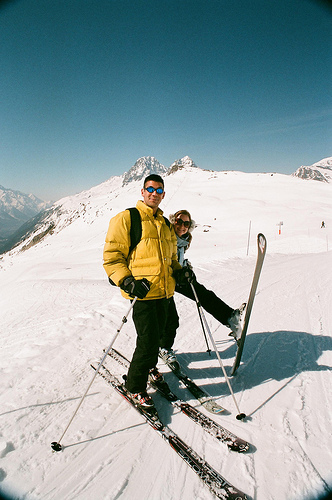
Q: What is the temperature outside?
A: Cold.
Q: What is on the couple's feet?
A: Skis.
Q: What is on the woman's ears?
A: Earmuffs.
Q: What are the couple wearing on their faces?
A: Sunglasses.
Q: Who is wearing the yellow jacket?
A: The man.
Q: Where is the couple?
A: On a ski slope.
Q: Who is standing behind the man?
A: The woman.